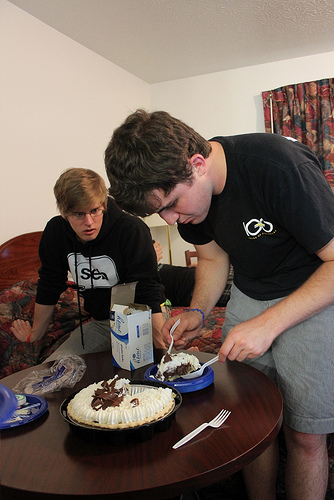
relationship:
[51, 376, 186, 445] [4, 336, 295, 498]
pie on table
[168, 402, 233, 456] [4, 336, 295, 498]
fork on table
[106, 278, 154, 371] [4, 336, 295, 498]
box on table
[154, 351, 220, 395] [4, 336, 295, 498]
plates on table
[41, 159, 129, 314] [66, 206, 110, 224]
boy wears glasses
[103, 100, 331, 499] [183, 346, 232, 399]
boy holding fork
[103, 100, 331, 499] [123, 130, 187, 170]
boy has hair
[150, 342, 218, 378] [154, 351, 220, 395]
pie on plates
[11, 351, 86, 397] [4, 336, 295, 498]
bag on table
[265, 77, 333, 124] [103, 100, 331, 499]
curtain behind boy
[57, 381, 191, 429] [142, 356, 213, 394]
pie on top of blue plate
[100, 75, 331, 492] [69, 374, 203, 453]
boy cuts cake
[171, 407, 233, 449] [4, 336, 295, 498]
fork on table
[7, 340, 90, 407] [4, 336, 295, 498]
bag sitting on table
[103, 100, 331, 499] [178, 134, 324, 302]
boy wearing shirt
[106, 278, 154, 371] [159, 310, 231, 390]
box has forks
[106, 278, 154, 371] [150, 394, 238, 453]
box has forks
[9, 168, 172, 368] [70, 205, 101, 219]
boy wearing glasses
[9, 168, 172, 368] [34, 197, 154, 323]
boy wearing hoodie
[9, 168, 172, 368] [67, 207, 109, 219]
boy wearing glasses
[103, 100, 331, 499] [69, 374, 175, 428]
boy cutting pie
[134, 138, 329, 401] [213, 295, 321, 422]
man wearing shorts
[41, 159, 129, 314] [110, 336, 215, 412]
boy looking at pie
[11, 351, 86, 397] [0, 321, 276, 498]
bag on table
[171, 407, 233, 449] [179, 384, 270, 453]
fork on table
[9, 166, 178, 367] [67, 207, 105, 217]
person wearing glasses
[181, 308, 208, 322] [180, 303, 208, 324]
bracelet on wrist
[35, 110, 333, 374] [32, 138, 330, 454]
boys in room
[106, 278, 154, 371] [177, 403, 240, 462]
box of forks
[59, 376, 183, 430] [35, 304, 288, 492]
pie on table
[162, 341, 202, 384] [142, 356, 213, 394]
pie on blue plate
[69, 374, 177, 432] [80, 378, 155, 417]
cake with whipped cream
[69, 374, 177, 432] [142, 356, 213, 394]
cake in blue plate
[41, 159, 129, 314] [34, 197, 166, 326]
boy wearing hoodie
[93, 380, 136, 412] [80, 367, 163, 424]
curls top of pie